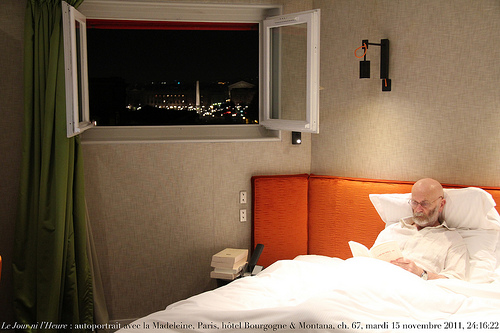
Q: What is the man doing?
A: Reading.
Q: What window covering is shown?
A: A curtain.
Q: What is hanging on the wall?
A: The light.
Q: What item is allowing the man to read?
A: Glasses.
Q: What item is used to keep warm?
A: The comforter.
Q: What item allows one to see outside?
A: The window.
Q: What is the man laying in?
A: The bed.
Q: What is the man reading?
A: A book.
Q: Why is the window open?
A: To let air in.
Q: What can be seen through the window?
A: A city skyline.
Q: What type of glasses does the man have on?
A: Wire frame.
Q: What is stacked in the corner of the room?
A: Books.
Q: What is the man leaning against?
A: Pillows.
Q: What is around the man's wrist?
A: Watch.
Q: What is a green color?
A: A window curtain.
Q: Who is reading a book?
A: A man.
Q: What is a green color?
A: Draperies.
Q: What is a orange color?
A: Headboard panels.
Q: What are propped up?
A: Pillows.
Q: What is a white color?
A: Comforter.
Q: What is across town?
A: Lights.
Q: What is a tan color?
A: The wallpaper.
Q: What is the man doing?
A: Reading.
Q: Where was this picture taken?
A: In the bedroom.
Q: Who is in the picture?
A: A man.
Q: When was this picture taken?
A: Night time.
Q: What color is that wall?
A: Brown.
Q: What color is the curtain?
A: Green.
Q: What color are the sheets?
A: White.